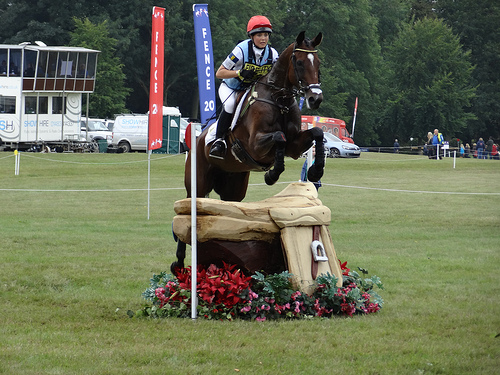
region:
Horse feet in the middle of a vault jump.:
[250, 128, 345, 183]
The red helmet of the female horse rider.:
[241, 13, 278, 32]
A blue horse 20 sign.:
[189, 3, 218, 120]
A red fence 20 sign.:
[146, 5, 171, 146]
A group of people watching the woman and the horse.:
[391, 125, 498, 161]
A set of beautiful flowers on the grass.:
[147, 271, 380, 312]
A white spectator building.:
[0, 33, 106, 153]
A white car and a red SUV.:
[319, 118, 364, 154]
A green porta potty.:
[163, 103, 180, 155]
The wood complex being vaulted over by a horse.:
[173, 178, 340, 286]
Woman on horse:
[209, 30, 280, 162]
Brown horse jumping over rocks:
[170, 27, 327, 274]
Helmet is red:
[244, 14, 272, 30]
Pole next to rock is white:
[187, 122, 202, 319]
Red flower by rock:
[226, 272, 241, 291]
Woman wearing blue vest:
[205, 30, 280, 161]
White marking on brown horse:
[307, 52, 314, 63]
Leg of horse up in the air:
[246, 130, 285, 185]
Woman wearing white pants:
[207, 27, 280, 159]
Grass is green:
[0, 149, 499, 374]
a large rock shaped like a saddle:
[165, 170, 360, 305]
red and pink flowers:
[143, 253, 270, 318]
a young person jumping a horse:
[176, 12, 341, 202]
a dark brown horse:
[171, 30, 340, 283]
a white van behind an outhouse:
[103, 109, 192, 150]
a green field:
[13, 178, 497, 363]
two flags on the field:
[127, 2, 224, 158]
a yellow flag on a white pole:
[7, 142, 24, 174]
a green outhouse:
[150, 98, 189, 163]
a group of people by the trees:
[385, 121, 498, 171]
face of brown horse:
[276, 27, 340, 104]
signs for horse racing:
[125, 82, 170, 149]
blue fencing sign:
[177, 45, 221, 115]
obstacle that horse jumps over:
[191, 206, 384, 283]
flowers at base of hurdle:
[211, 275, 340, 318]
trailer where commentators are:
[2, 47, 112, 126]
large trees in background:
[392, 50, 477, 112]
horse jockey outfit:
[231, 36, 273, 73]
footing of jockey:
[188, 124, 233, 165]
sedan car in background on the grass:
[322, 127, 367, 168]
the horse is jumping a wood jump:
[165, 30, 348, 322]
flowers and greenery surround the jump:
[139, 262, 379, 319]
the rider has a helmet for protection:
[244, 13, 274, 36]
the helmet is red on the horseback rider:
[247, 15, 273, 37]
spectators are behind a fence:
[398, 128, 498, 163]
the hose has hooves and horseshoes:
[262, 162, 332, 186]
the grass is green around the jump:
[3, 155, 497, 367]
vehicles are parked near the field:
[85, 106, 357, 162]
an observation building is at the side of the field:
[3, 39, 101, 156]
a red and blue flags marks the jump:
[148, 1, 215, 331]